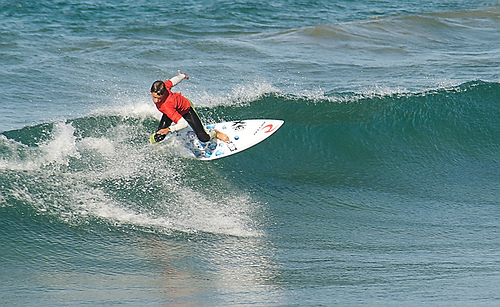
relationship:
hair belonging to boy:
[148, 78, 168, 97] [146, 68, 231, 147]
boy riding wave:
[146, 68, 231, 147] [2, 75, 482, 237]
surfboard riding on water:
[176, 117, 286, 162] [8, 10, 484, 295]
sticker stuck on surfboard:
[230, 119, 246, 132] [176, 117, 286, 162]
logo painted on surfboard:
[252, 120, 265, 136] [176, 117, 286, 162]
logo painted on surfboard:
[254, 121, 279, 136] [176, 117, 286, 162]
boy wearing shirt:
[146, 68, 231, 147] [153, 77, 192, 124]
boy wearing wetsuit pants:
[146, 68, 231, 147] [152, 103, 213, 143]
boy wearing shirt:
[146, 68, 231, 147] [152, 72, 188, 132]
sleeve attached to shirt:
[167, 72, 186, 83] [152, 72, 188, 132]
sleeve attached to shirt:
[166, 116, 189, 132] [152, 72, 188, 132]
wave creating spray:
[2, 75, 482, 237] [3, 60, 458, 240]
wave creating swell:
[2, 75, 482, 237] [2, 85, 482, 205]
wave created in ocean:
[2, 75, 482, 237] [0, 0, 499, 307]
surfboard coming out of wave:
[176, 117, 286, 162] [2, 75, 482, 237]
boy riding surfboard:
[146, 68, 231, 147] [176, 117, 286, 162]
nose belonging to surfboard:
[266, 116, 285, 134] [176, 117, 286, 162]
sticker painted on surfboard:
[230, 120, 249, 131] [176, 117, 286, 162]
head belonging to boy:
[148, 79, 168, 106] [145, 67, 231, 145]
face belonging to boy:
[150, 89, 165, 106] [146, 68, 231, 147]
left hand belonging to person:
[156, 127, 170, 136] [146, 68, 232, 145]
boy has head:
[146, 68, 231, 147] [142, 74, 171, 106]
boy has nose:
[146, 68, 231, 147] [152, 93, 159, 105]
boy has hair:
[146, 68, 231, 147] [148, 80, 171, 101]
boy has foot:
[146, 68, 231, 147] [208, 127, 231, 143]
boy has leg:
[146, 68, 231, 147] [179, 109, 228, 147]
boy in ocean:
[146, 68, 231, 147] [0, 0, 499, 307]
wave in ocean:
[0, 0, 499, 242] [15, 62, 491, 225]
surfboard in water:
[176, 117, 286, 162] [70, 40, 355, 241]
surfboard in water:
[167, 115, 287, 163] [0, 0, 500, 303]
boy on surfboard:
[146, 68, 231, 147] [167, 117, 281, 161]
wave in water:
[0, 0, 499, 242] [0, 0, 500, 303]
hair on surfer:
[148, 77, 172, 100] [148, 66, 220, 150]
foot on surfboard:
[206, 126, 236, 144] [176, 117, 286, 162]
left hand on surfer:
[149, 122, 170, 136] [149, 66, 234, 149]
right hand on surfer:
[170, 69, 192, 81] [145, 73, 234, 150]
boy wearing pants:
[146, 68, 231, 147] [151, 103, 213, 147]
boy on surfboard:
[149, 65, 237, 150] [167, 117, 281, 161]